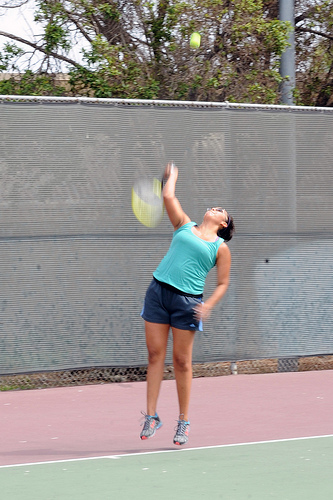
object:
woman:
[138, 161, 234, 447]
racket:
[131, 160, 170, 232]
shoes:
[137, 410, 190, 446]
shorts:
[140, 277, 204, 334]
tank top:
[151, 220, 224, 296]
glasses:
[206, 205, 228, 212]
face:
[204, 206, 227, 219]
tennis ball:
[189, 31, 201, 51]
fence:
[0, 94, 333, 382]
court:
[0, 353, 333, 499]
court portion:
[0, 432, 333, 498]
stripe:
[1, 432, 333, 474]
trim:
[198, 296, 204, 332]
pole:
[274, 0, 300, 223]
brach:
[0, 28, 91, 73]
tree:
[1, 1, 333, 107]